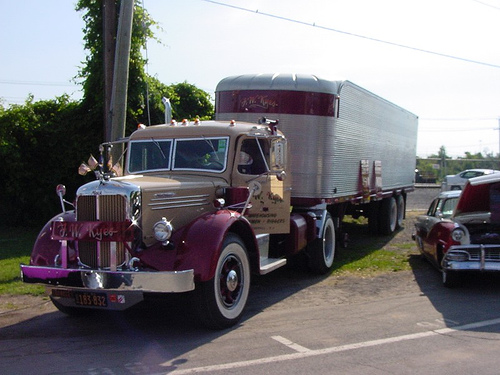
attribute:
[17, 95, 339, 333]
tractor — purple, tan, classic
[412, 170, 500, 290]
classic car — red, white, old, parked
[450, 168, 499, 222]
hood — open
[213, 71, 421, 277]
trailer — classic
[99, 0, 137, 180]
poles — large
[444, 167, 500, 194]
car — white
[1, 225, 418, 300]
grass — patch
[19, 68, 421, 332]
tractor-trailer — parked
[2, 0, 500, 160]
sky — clear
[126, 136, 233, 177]
trim — chrome